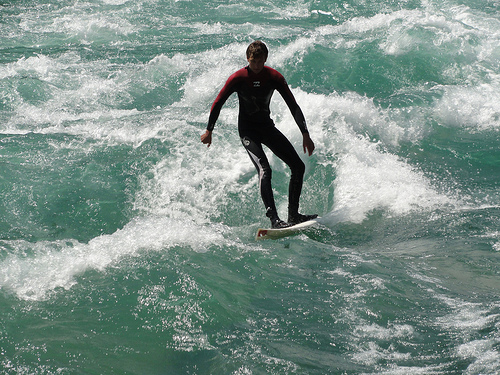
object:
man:
[198, 39, 319, 229]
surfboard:
[256, 215, 324, 238]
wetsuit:
[208, 66, 307, 222]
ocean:
[0, 0, 500, 375]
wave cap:
[331, 125, 437, 213]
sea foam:
[67, 235, 143, 267]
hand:
[200, 130, 214, 148]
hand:
[302, 136, 315, 156]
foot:
[271, 217, 289, 229]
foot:
[289, 212, 323, 222]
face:
[249, 55, 266, 74]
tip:
[256, 226, 271, 238]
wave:
[307, 5, 476, 60]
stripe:
[250, 153, 268, 189]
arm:
[276, 72, 315, 157]